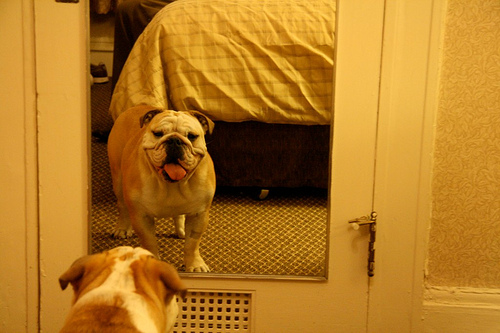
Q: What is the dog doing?
A: Looking in the mirror.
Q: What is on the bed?
A: A comforter.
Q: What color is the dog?
A: Brown and white.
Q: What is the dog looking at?
A: Himself in the mirror.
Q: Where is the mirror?
A: On the door.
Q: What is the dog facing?
A: The mirror.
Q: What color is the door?
A: White.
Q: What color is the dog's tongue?
A: Pink.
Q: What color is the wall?
A: Beige.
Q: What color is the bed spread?
A: Yellow.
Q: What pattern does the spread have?
A: Light lines.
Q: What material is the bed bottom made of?
A: Wood.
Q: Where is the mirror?
A: On the closet door.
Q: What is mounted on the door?
A: Mirror.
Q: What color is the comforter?
A: White with stripes.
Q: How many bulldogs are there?
A: One.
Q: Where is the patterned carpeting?
A: In the reflection.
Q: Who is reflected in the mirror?
A: The dog.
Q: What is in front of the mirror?
A: Dog.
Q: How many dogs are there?
A: One.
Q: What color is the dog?
A: Brown and white.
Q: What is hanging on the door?
A: A mirror.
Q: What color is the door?
A: White.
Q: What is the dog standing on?
A: Carpet.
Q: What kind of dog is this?
A: Bull dog.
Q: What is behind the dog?
A: A bed.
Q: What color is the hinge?
A: Gold.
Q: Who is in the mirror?
A: Dog.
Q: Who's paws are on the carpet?
A: Dog.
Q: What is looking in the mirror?
A: A dog.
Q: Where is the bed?
A: Behind the dog.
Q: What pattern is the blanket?
A: Checkered.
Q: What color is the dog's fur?
A: White and brown.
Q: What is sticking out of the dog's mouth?
A: Its tongue.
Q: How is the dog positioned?
A: Standing.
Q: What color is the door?
A: White.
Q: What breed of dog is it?
A: Bulldog.